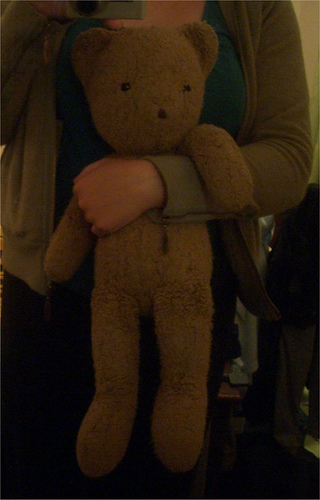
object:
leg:
[155, 288, 214, 386]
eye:
[122, 83, 130, 91]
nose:
[159, 107, 167, 118]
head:
[73, 18, 220, 154]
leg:
[91, 289, 139, 401]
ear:
[71, 26, 114, 83]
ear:
[178, 20, 219, 78]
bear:
[45, 19, 260, 477]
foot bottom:
[76, 414, 133, 479]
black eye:
[183, 85, 190, 90]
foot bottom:
[151, 393, 206, 474]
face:
[92, 42, 204, 151]